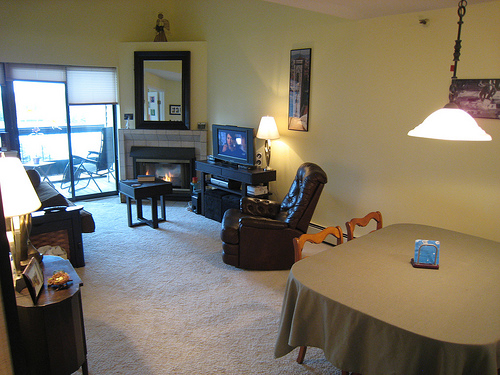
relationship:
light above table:
[406, 109, 495, 144] [271, 222, 499, 374]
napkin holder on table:
[409, 238, 441, 271] [271, 222, 499, 374]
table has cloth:
[271, 222, 499, 374] [272, 222, 499, 372]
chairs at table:
[291, 209, 383, 263] [271, 222, 499, 374]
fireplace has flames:
[128, 142, 197, 200] [163, 173, 173, 185]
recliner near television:
[218, 162, 327, 275] [208, 123, 256, 166]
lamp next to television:
[256, 114, 282, 174] [208, 123, 256, 166]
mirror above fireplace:
[143, 59, 183, 122] [128, 142, 197, 200]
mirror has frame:
[143, 59, 183, 122] [132, 50, 192, 131]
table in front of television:
[117, 173, 172, 230] [208, 123, 256, 166]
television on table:
[208, 123, 256, 166] [194, 153, 278, 221]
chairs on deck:
[60, 122, 117, 193] [24, 160, 121, 201]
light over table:
[406, 109, 495, 144] [271, 222, 499, 374]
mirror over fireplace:
[143, 59, 183, 122] [128, 142, 197, 200]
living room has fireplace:
[1, 0, 353, 373] [128, 142, 197, 200]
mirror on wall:
[143, 59, 183, 122] [116, 40, 210, 132]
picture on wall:
[287, 45, 310, 134] [209, 5, 499, 247]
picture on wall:
[450, 77, 500, 121] [209, 5, 499, 247]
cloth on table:
[272, 222, 499, 372] [271, 222, 499, 374]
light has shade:
[406, 109, 495, 144] [405, 109, 494, 141]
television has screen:
[208, 123, 256, 166] [218, 128, 248, 161]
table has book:
[117, 173, 172, 230] [137, 174, 157, 184]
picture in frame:
[31, 272, 42, 290] [19, 254, 44, 307]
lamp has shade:
[256, 114, 282, 174] [253, 115, 283, 141]